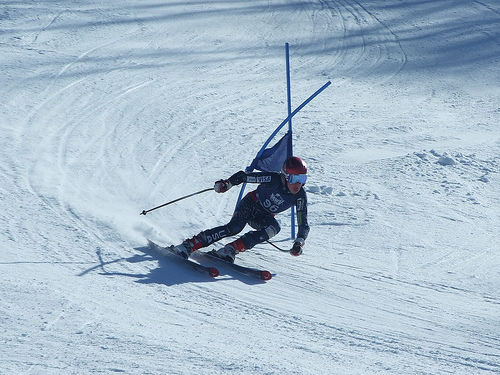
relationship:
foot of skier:
[168, 242, 187, 254] [144, 133, 356, 318]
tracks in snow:
[35, 88, 178, 184] [339, 65, 481, 310]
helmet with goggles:
[275, 147, 325, 185] [284, 171, 306, 183]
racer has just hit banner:
[167, 156, 310, 263] [232, 77, 334, 228]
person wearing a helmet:
[192, 156, 322, 278] [282, 155, 310, 193]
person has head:
[192, 156, 322, 278] [280, 155, 305, 195]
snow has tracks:
[1, 2, 497, 370] [278, 0, 406, 77]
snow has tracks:
[1, 2, 497, 370] [10, 55, 220, 222]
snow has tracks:
[1, 2, 497, 370] [127, 248, 497, 372]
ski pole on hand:
[138, 180, 216, 239] [197, 165, 237, 203]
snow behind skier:
[1, 2, 497, 370] [170, 155, 311, 265]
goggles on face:
[280, 172, 307, 184] [284, 175, 302, 194]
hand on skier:
[286, 242, 308, 257] [132, 124, 322, 293]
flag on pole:
[247, 129, 292, 174] [232, 80, 329, 208]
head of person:
[282, 152, 307, 196] [110, 107, 422, 362]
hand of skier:
[207, 165, 240, 203] [155, 101, 320, 285]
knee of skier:
[224, 222, 247, 236] [170, 155, 311, 265]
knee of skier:
[269, 222, 281, 233] [170, 155, 311, 265]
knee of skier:
[224, 212, 254, 237] [205, 123, 328, 266]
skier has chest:
[170, 155, 311, 265] [236, 177, 312, 237]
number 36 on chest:
[263, 198, 279, 213] [236, 177, 312, 237]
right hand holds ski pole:
[212, 177, 231, 195] [137, 188, 215, 218]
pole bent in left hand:
[283, 41, 296, 238] [286, 241, 306, 258]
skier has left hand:
[170, 155, 311, 265] [286, 241, 306, 258]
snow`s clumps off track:
[308, 144, 498, 216] [304, 0, 407, 91]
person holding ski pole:
[146, 160, 358, 294] [137, 184, 216, 218]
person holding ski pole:
[146, 160, 358, 294] [266, 239, 292, 256]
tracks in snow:
[35, 88, 178, 184] [1, 2, 497, 370]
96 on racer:
[262, 196, 277, 213] [177, 156, 310, 270]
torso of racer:
[253, 177, 291, 212] [177, 156, 310, 270]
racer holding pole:
[167, 156, 310, 263] [138, 187, 218, 214]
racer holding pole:
[167, 156, 310, 263] [266, 236, 293, 254]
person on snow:
[192, 156, 322, 278] [1, 2, 497, 370]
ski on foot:
[194, 247, 271, 279] [210, 247, 235, 263]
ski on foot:
[147, 238, 219, 277] [168, 242, 187, 254]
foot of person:
[210, 247, 235, 263] [192, 156, 322, 278]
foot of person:
[168, 242, 187, 254] [192, 156, 322, 278]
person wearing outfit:
[192, 156, 322, 278] [182, 169, 311, 251]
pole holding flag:
[283, 41, 296, 238] [247, 126, 297, 181]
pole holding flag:
[136, 185, 226, 219] [247, 126, 297, 181]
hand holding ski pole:
[211, 174, 234, 196] [131, 181, 234, 230]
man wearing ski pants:
[174, 154, 310, 261] [182, 195, 281, 269]